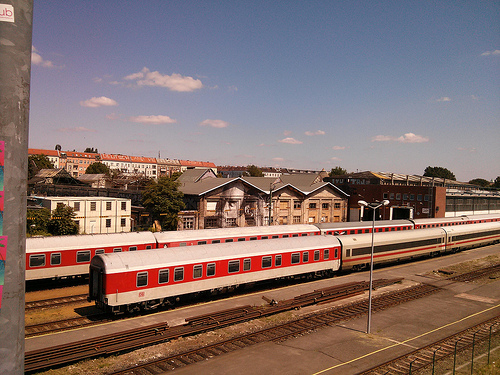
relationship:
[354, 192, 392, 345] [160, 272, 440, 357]
pole light by train tracks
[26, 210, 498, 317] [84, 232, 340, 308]
train with cabin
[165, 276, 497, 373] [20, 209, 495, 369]
road in station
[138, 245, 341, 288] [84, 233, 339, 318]
windows of train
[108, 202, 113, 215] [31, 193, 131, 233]
window of building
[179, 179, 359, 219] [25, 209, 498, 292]
house near train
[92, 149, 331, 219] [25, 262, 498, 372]
building by tracks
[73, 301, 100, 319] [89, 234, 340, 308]
shadow of cabin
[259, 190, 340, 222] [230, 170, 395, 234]
window in building